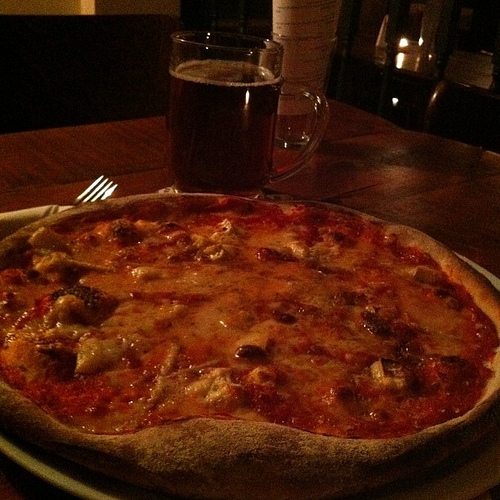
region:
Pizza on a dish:
[1, 181, 497, 492]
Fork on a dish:
[45, 170, 120, 201]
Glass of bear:
[158, 22, 330, 199]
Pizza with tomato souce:
[1, 186, 498, 476]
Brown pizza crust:
[0, 385, 499, 495]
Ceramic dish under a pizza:
[0, 181, 496, 494]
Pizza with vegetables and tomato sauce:
[7, 190, 493, 457]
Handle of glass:
[265, 75, 328, 185]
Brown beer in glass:
[167, 67, 275, 189]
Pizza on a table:
[6, 108, 499, 489]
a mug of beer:
[167, 33, 310, 183]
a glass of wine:
[356, 10, 444, 134]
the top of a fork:
[74, 175, 118, 210]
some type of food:
[3, 242, 467, 427]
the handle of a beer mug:
[273, 76, 337, 186]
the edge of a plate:
[1, 453, 113, 493]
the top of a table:
[361, 146, 461, 206]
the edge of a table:
[21, 120, 144, 142]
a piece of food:
[59, 322, 107, 365]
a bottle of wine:
[278, 1, 329, 96]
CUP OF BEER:
[143, 31, 325, 194]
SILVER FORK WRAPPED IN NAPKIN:
[0, 170, 126, 232]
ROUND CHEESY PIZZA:
[6, 188, 496, 495]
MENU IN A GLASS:
[270, 5, 337, 147]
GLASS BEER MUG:
[160, 25, 326, 179]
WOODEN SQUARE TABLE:
[0, 103, 499, 248]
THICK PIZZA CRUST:
[0, 404, 499, 499]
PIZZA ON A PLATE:
[0, 188, 495, 498]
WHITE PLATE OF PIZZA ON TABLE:
[0, 207, 498, 499]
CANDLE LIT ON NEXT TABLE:
[384, 29, 447, 75]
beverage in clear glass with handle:
[150, 25, 336, 195]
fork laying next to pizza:
[10, 165, 121, 265]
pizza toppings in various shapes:
[36, 310, 421, 420]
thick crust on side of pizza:
[42, 405, 429, 488]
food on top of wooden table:
[65, 52, 455, 334]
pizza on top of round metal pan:
[5, 196, 490, 483]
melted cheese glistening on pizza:
[72, 240, 322, 391]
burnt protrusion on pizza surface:
[102, 206, 162, 251]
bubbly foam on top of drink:
[155, 46, 285, 108]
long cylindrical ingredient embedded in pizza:
[123, 323, 201, 425]